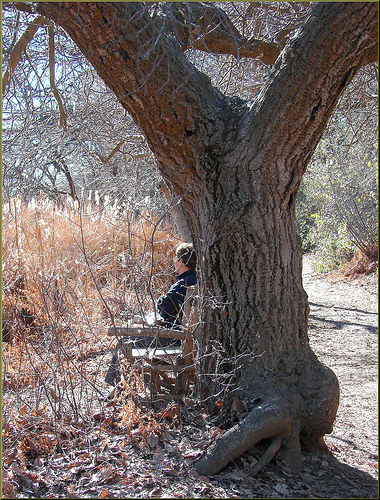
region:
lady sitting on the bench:
[102, 228, 205, 377]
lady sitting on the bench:
[80, 210, 224, 440]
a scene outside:
[3, 2, 378, 498]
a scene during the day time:
[3, 0, 376, 498]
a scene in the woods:
[7, 4, 375, 496]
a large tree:
[24, 1, 368, 474]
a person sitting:
[121, 236, 214, 399]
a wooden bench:
[103, 285, 224, 414]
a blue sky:
[0, 12, 135, 206]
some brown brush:
[1, 170, 189, 362]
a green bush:
[303, 142, 357, 289]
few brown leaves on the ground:
[1, 372, 249, 499]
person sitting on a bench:
[101, 242, 194, 402]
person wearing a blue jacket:
[156, 267, 197, 327]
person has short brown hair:
[175, 243, 194, 270]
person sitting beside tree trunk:
[148, 184, 342, 480]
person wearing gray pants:
[104, 336, 178, 384]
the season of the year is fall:
[1, 2, 377, 495]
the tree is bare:
[2, 2, 374, 481]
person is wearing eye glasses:
[170, 254, 183, 261]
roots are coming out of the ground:
[193, 367, 339, 476]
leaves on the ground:
[0, 397, 329, 499]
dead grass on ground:
[43, 237, 82, 330]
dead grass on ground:
[6, 199, 30, 330]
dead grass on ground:
[29, 201, 56, 306]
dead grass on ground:
[62, 182, 96, 300]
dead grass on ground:
[99, 199, 132, 280]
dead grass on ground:
[143, 201, 173, 270]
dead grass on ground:
[344, 239, 377, 285]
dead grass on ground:
[4, 331, 46, 383]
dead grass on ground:
[112, 378, 160, 445]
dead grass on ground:
[13, 277, 61, 314]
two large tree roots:
[197, 407, 302, 476]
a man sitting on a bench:
[100, 241, 196, 402]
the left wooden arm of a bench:
[108, 327, 185, 337]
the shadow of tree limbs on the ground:
[309, 297, 379, 331]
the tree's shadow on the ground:
[204, 450, 378, 498]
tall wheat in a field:
[1, 193, 177, 320]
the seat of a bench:
[128, 345, 185, 363]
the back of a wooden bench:
[184, 285, 197, 364]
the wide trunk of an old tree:
[151, 153, 337, 474]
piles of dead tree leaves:
[3, 405, 339, 496]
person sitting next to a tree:
[41, 107, 290, 438]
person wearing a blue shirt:
[145, 261, 201, 332]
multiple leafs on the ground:
[37, 391, 223, 496]